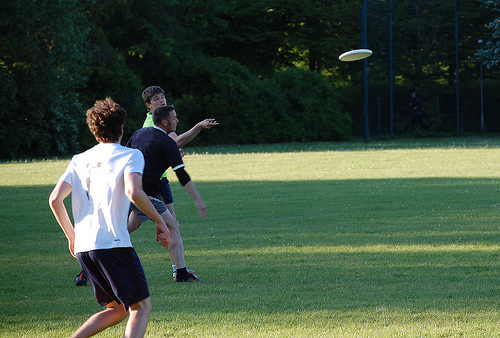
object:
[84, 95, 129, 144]
head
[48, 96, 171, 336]
man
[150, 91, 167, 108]
face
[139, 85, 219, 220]
person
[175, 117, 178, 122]
nose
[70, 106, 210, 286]
guy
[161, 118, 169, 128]
ear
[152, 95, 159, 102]
eyes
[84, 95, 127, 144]
hair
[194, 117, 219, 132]
hand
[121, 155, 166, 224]
arm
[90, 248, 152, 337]
legs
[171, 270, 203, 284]
foot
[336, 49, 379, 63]
frisbee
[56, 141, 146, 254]
shirt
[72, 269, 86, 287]
shoe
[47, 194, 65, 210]
left elbow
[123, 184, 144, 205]
right elbow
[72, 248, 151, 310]
shorts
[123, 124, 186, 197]
shirt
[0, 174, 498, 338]
shadow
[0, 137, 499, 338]
field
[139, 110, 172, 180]
shirt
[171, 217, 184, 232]
right knee